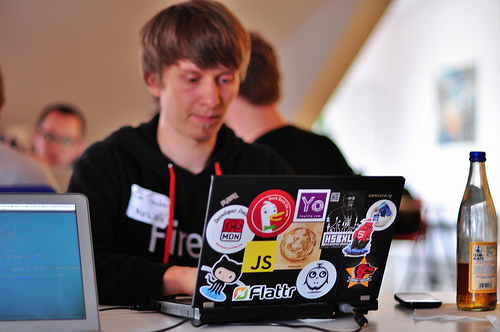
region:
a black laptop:
[128, 110, 442, 330]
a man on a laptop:
[44, 6, 471, 331]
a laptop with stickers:
[147, 152, 439, 328]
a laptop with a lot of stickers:
[84, 138, 432, 330]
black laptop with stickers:
[115, 157, 431, 329]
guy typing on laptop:
[43, 5, 440, 321]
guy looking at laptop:
[44, 10, 417, 330]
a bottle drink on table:
[408, 125, 498, 330]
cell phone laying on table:
[386, 286, 433, 328]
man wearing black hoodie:
[67, 4, 385, 284]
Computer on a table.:
[141, 142, 397, 320]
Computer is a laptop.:
[136, 153, 402, 323]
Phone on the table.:
[392, 272, 442, 315]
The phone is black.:
[393, 277, 442, 308]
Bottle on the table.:
[442, 144, 497, 324]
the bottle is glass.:
[442, 145, 495, 316]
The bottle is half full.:
[449, 132, 498, 316]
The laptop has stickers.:
[149, 157, 386, 324]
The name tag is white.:
[122, 170, 174, 234]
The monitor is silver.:
[3, 203, 108, 329]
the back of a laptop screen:
[192, 173, 405, 321]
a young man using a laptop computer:
[70, 0, 404, 330]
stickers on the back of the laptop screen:
[197, 171, 405, 311]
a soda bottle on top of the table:
[455, 151, 499, 309]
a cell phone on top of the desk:
[392, 291, 442, 309]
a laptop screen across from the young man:
[0, 191, 99, 329]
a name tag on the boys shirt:
[126, 183, 170, 230]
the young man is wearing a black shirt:
[66, 113, 261, 303]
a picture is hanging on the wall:
[434, 64, 477, 144]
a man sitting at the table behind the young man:
[0, 68, 63, 195]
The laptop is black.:
[151, 163, 392, 329]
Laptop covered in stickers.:
[147, 168, 397, 313]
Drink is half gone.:
[440, 135, 499, 322]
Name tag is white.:
[130, 168, 172, 240]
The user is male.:
[56, 1, 290, 313]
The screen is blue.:
[2, 199, 82, 326]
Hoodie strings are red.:
[156, 155, 176, 262]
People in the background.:
[6, 10, 306, 205]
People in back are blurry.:
[3, 6, 328, 185]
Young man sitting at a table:
[62, 0, 324, 308]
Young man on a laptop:
[67, 1, 312, 307]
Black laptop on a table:
[156, 169, 405, 329]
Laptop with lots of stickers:
[145, 174, 407, 327]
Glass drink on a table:
[454, 149, 499, 311]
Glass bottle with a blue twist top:
[454, 150, 499, 321]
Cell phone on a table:
[394, 290, 444, 310]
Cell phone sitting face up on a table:
[391, 289, 444, 311]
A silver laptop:
[0, 192, 97, 329]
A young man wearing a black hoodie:
[69, 1, 300, 305]